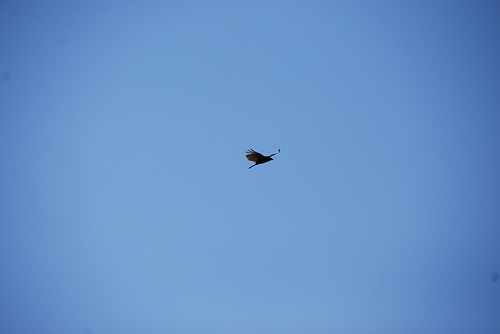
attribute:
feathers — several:
[233, 133, 263, 168]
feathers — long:
[233, 147, 285, 165]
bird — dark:
[195, 123, 293, 198]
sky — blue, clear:
[68, 179, 172, 269]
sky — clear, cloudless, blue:
[97, 131, 179, 261]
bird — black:
[243, 145, 282, 174]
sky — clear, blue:
[167, 44, 394, 144]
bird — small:
[246, 146, 281, 173]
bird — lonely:
[245, 143, 283, 170]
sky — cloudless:
[6, 5, 498, 326]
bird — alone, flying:
[239, 140, 281, 172]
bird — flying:
[235, 143, 292, 175]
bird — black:
[241, 141, 281, 171]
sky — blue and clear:
[79, 81, 343, 318]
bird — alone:
[239, 145, 284, 169]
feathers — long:
[249, 154, 267, 161]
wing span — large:
[238, 141, 266, 168]